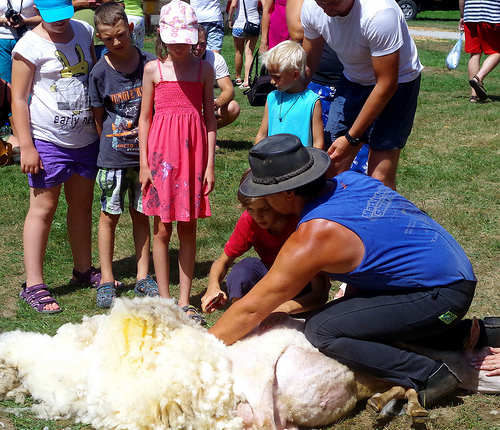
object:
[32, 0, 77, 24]
blue cap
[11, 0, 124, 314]
girl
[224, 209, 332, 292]
red shirt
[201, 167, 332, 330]
boy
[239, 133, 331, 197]
hat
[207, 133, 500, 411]
man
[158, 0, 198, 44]
pink hat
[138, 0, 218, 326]
skinny girl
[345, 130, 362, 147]
watch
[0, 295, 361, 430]
wool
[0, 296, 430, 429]
sheep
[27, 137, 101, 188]
purple shorts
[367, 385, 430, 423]
hooves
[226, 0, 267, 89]
woman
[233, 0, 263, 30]
white shirt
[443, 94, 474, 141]
grass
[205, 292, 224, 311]
scissors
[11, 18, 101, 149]
shirt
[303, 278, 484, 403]
pants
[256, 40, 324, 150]
boy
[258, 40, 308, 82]
blonde hair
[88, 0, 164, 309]
kid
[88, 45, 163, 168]
dark blue shirt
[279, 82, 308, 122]
necklace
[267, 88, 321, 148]
light blue shirt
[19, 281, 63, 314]
purple sandals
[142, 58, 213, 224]
pink dress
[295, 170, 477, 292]
blue shirt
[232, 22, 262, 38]
blue shorts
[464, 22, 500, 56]
red shorts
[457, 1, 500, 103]
person